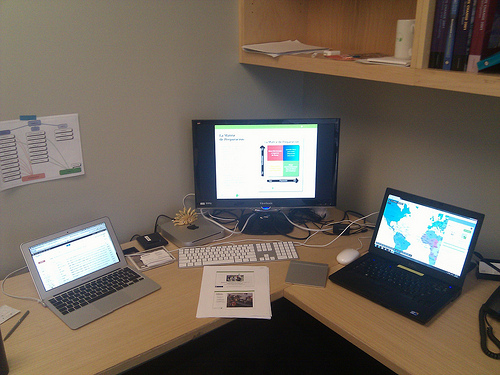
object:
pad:
[285, 260, 329, 288]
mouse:
[336, 248, 360, 266]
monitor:
[214, 122, 317, 199]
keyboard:
[178, 241, 300, 269]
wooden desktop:
[0, 209, 500, 375]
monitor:
[374, 193, 479, 279]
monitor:
[27, 221, 121, 291]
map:
[374, 194, 450, 267]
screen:
[373, 193, 478, 278]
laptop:
[329, 186, 487, 328]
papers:
[195, 266, 272, 321]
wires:
[129, 193, 379, 250]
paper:
[195, 266, 272, 320]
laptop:
[18, 215, 162, 330]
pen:
[2, 310, 29, 342]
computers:
[188, 117, 485, 326]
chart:
[0, 113, 86, 190]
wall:
[0, 0, 500, 279]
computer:
[191, 117, 341, 236]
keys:
[179, 241, 299, 267]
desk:
[2, 206, 499, 375]